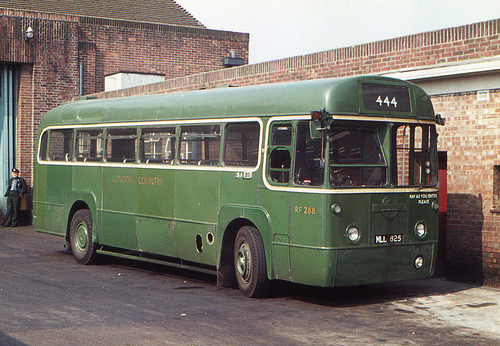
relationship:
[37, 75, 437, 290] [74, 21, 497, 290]
bus parked by wall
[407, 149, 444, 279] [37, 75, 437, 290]
door next to bus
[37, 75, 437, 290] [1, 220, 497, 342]
bus on road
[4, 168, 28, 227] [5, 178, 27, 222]
guard wearing uniform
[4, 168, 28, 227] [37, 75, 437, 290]
guard behind bus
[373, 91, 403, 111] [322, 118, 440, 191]
numbers above windshield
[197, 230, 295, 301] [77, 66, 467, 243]
tire on bus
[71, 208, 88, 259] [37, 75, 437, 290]
tire on bus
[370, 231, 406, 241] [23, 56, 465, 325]
plate attached to bus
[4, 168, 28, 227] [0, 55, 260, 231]
guard leaning against building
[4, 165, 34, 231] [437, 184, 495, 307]
guard standing by gate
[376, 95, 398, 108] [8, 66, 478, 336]
numbers on bus